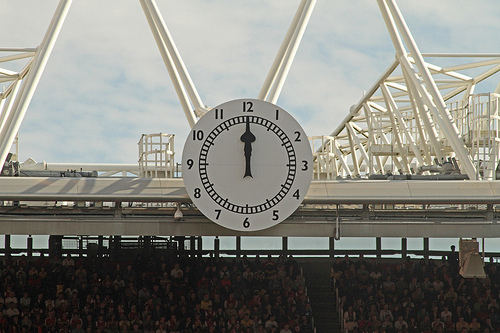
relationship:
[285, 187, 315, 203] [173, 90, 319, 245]
number on clock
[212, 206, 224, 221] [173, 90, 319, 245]
number on clock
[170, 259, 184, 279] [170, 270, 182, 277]
person in shirt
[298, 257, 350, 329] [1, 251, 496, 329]
stairs in seating area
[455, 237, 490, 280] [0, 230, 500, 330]
light in stadium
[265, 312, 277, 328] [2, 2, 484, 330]
patron in stadium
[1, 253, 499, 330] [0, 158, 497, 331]
stands in stadium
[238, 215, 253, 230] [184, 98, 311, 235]
number on clock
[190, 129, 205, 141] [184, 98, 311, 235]
number painted on clock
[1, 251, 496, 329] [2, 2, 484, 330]
seating area built in stadium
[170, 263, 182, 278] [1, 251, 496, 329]
person sitting in seating area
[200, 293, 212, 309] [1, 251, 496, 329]
person sitting in seating area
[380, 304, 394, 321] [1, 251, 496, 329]
person sitting in seating area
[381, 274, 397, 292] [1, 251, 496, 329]
person sitting in seating area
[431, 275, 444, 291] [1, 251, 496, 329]
person sitting in seating area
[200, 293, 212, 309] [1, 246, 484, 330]
person sitting in stands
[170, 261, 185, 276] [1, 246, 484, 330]
person sitting in stands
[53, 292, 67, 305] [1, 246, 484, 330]
person sitting in stands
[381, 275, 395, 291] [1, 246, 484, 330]
person sitting in stands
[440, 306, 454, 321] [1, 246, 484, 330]
person sitting in stands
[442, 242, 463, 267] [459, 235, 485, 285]
person standing next to pole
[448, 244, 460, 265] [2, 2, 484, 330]
man standing inside stadium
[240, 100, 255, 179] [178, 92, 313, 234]
12:00 shown on clock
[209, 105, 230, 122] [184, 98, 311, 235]
11 painted on clock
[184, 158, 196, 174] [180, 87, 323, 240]
9 painted on clock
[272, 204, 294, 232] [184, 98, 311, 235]
number painted on clock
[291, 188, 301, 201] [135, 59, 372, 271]
number 4 painted on clock